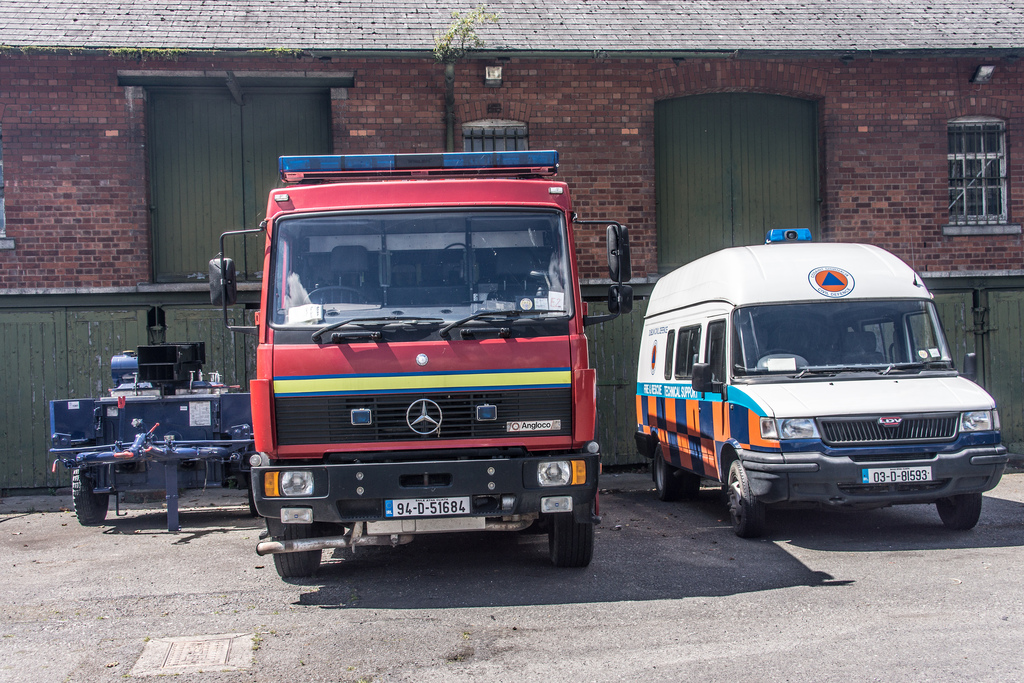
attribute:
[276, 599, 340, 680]
pavement — concrete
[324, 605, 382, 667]
pavement — concrete 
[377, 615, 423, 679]
pavement — concrete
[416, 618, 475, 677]
pavement — concrete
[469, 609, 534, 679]
pavement — concrete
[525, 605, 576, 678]
pavement — concrete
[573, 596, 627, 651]
pavement — concrete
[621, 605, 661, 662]
pavement — concrete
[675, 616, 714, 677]
pavement — concrete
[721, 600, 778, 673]
pavement — concrete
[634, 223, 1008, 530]
vehicle — white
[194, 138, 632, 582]
vehicle — red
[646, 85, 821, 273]
doors — green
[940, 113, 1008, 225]
window — white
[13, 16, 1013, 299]
building — red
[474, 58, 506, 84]
light — mounted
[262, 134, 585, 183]
light — blue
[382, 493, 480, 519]
plate — white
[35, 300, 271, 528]
trailer — blue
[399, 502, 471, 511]
lettering — black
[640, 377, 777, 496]
stripes — orange and blue